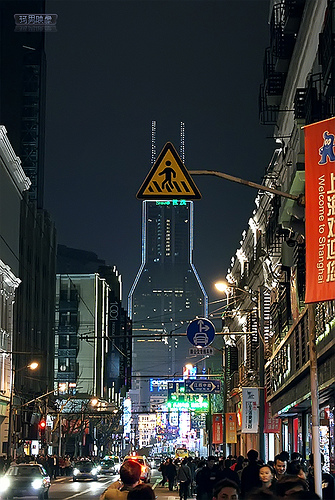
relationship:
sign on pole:
[133, 141, 203, 202] [186, 168, 222, 174]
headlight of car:
[31, 480, 42, 490] [1, 459, 61, 491]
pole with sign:
[183, 168, 297, 200] [133, 141, 202, 198]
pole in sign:
[183, 168, 297, 200] [133, 141, 203, 202]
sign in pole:
[173, 307, 252, 419] [248, 303, 274, 464]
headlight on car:
[31, 480, 42, 490] [1, 459, 53, 498]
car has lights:
[103, 406, 223, 484] [154, 188, 209, 237]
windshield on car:
[9, 460, 41, 482] [2, 452, 57, 497]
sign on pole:
[133, 141, 202, 198] [183, 168, 297, 200]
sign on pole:
[133, 141, 203, 202] [183, 168, 297, 200]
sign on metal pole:
[133, 141, 203, 202] [211, 171, 301, 201]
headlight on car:
[70, 464, 84, 478] [69, 448, 106, 484]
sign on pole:
[133, 141, 202, 198] [136, 142, 301, 206]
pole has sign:
[183, 160, 296, 206] [126, 138, 208, 201]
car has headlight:
[73, 460, 90, 479] [86, 466, 97, 479]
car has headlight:
[73, 460, 90, 479] [74, 467, 83, 477]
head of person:
[256, 462, 273, 489] [255, 463, 276, 493]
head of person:
[271, 455, 287, 470] [239, 434, 324, 474]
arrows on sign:
[195, 316, 208, 330] [193, 316, 220, 342]